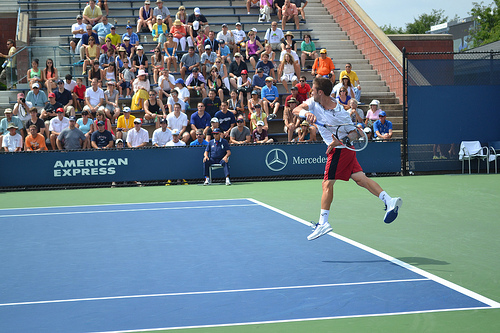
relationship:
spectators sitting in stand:
[78, 21, 303, 125] [29, 13, 369, 126]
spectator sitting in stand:
[186, 104, 213, 134] [4, 4, 394, 129]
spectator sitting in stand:
[246, 85, 268, 117] [4, 4, 394, 129]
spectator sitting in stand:
[229, 51, 248, 79] [4, 4, 394, 129]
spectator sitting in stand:
[115, 46, 128, 70] [4, 4, 394, 129]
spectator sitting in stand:
[290, 71, 310, 104] [4, 4, 394, 129]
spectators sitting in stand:
[1, 0, 393, 155] [1, 0, 404, 193]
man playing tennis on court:
[285, 74, 400, 239] [1, 195, 487, 332]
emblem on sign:
[259, 145, 295, 182] [5, 135, 402, 186]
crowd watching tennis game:
[19, 8, 374, 130] [47, 48, 493, 332]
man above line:
[285, 74, 400, 239] [252, 173, 499, 303]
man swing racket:
[285, 74, 400, 239] [318, 118, 371, 151]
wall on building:
[382, 43, 459, 148] [299, 8, 494, 190]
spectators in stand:
[76, 11, 296, 118] [29, 13, 369, 126]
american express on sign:
[51, 155, 128, 177] [0, 143, 403, 188]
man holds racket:
[274, 62, 421, 267] [301, 100, 391, 166]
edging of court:
[95, 141, 496, 247] [0, 172, 500, 330]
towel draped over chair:
[457, 140, 485, 159] [457, 138, 484, 172]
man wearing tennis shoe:
[285, 74, 400, 239] [379, 195, 406, 222]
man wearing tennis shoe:
[285, 74, 400, 239] [305, 220, 330, 245]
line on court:
[133, 267, 303, 319] [0, 172, 500, 330]